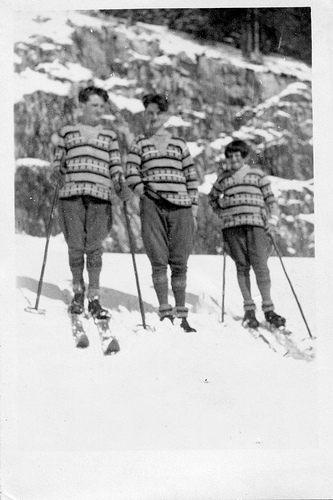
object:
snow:
[14, 7, 312, 498]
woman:
[206, 135, 289, 334]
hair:
[222, 131, 249, 159]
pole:
[29, 171, 61, 310]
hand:
[48, 160, 69, 188]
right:
[33, 216, 80, 432]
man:
[124, 84, 202, 339]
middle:
[121, 55, 214, 420]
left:
[41, 112, 139, 460]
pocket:
[50, 121, 129, 206]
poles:
[122, 188, 150, 331]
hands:
[111, 167, 131, 208]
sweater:
[121, 130, 201, 208]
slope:
[57, 11, 312, 100]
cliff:
[16, 8, 315, 257]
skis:
[48, 80, 133, 320]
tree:
[104, 7, 313, 65]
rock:
[11, 80, 77, 157]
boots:
[241, 302, 259, 330]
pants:
[136, 190, 200, 322]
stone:
[126, 48, 236, 140]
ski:
[211, 286, 274, 351]